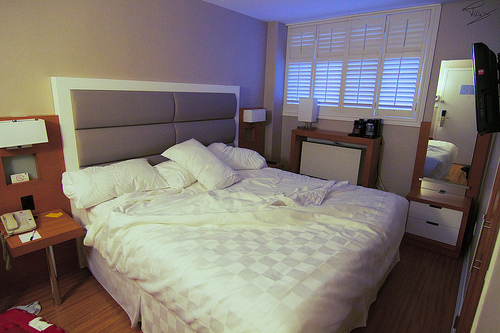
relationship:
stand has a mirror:
[405, 186, 472, 258] [424, 60, 477, 186]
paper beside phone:
[18, 229, 40, 246] [1, 207, 37, 237]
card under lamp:
[9, 171, 31, 182] [1, 119, 49, 148]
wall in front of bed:
[1, 1, 289, 118] [86, 167, 406, 333]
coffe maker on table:
[349, 118, 382, 136] [288, 127, 383, 186]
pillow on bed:
[155, 160, 197, 191] [86, 167, 406, 333]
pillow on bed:
[63, 154, 168, 211] [86, 167, 406, 333]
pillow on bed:
[206, 143, 267, 170] [86, 167, 406, 333]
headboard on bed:
[51, 77, 240, 171] [86, 167, 406, 333]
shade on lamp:
[298, 98, 318, 122] [298, 96, 320, 130]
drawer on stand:
[409, 201, 464, 229] [405, 186, 472, 258]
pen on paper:
[31, 229, 36, 240] [18, 229, 40, 246]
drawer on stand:
[406, 216, 461, 248] [405, 186, 472, 258]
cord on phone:
[1, 230, 12, 271] [1, 207, 37, 237]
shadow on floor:
[57, 276, 87, 304] [356, 242, 461, 333]